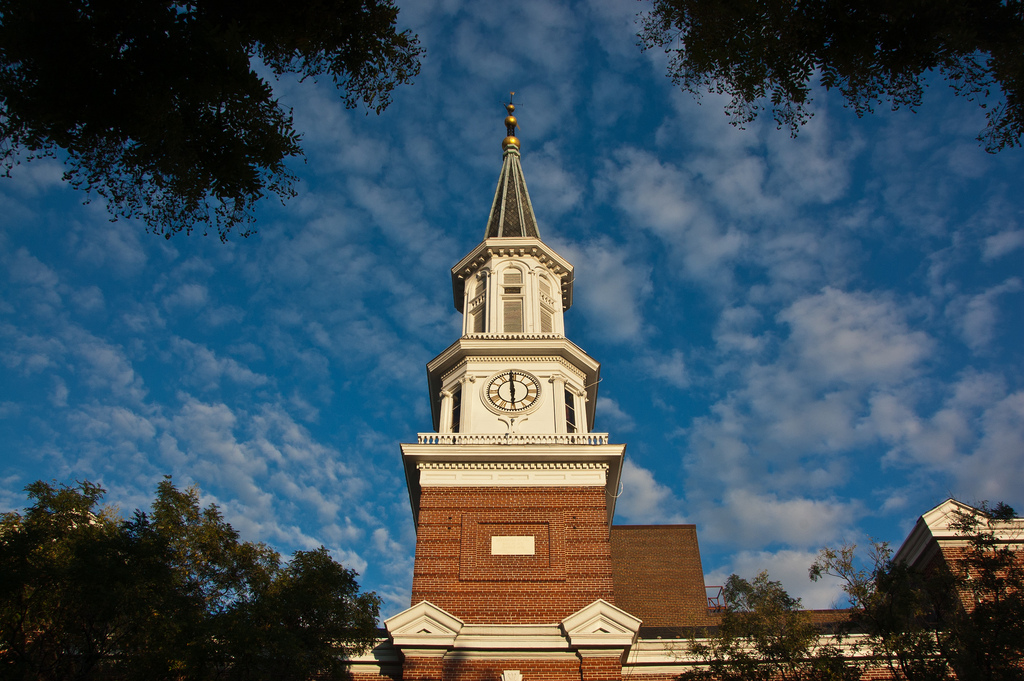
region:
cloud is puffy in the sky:
[173, 398, 273, 506]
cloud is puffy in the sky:
[70, 336, 143, 400]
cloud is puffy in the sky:
[3, 328, 71, 373]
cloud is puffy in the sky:
[48, 379, 71, 412]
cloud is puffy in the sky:
[164, 285, 209, 315]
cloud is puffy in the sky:
[72, 221, 146, 279]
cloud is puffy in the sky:
[342, 174, 460, 277]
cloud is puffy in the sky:
[533, 218, 658, 349]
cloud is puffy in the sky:
[613, 459, 686, 524]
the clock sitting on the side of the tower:
[480, 366, 537, 412]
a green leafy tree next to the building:
[3, 484, 400, 678]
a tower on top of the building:
[411, 79, 618, 441]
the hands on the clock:
[503, 372, 519, 410]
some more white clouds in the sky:
[27, 221, 361, 488]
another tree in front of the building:
[651, 496, 1022, 677]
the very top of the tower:
[493, 88, 522, 139]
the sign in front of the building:
[461, 505, 566, 578]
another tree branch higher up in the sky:
[0, 15, 416, 227]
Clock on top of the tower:
[477, 364, 548, 421]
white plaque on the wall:
[483, 527, 540, 562]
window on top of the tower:
[498, 247, 528, 327]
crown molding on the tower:
[384, 595, 474, 653]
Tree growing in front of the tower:
[727, 550, 842, 655]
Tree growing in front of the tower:
[43, 467, 177, 645]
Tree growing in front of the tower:
[954, 508, 1021, 670]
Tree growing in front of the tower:
[694, 565, 844, 676]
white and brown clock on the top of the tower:
[483, 374, 537, 416]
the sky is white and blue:
[574, 140, 929, 441]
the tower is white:
[403, 54, 670, 525]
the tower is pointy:
[478, 76, 693, 359]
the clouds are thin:
[166, 210, 433, 504]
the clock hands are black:
[434, 342, 622, 473]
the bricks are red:
[387, 424, 673, 669]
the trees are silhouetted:
[111, 54, 330, 254]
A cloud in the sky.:
[259, 386, 305, 429]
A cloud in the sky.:
[230, 406, 307, 446]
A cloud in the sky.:
[604, 144, 757, 285]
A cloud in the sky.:
[549, 209, 658, 362]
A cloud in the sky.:
[514, 80, 579, 178]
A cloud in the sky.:
[740, 258, 938, 373]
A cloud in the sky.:
[663, 490, 899, 577]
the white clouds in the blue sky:
[0, 0, 1018, 626]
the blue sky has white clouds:
[0, 0, 1022, 632]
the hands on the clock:
[485, 367, 539, 410]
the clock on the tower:
[403, 83, 623, 628]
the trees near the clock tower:
[0, 2, 1021, 679]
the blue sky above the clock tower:
[1, 3, 1020, 678]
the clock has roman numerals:
[485, 372, 539, 412]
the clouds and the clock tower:
[2, 0, 1018, 677]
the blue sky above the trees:
[0, 0, 1022, 676]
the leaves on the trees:
[1, 0, 1020, 677]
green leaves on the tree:
[781, 54, 807, 93]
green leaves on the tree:
[142, 651, 168, 675]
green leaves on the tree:
[173, 585, 237, 653]